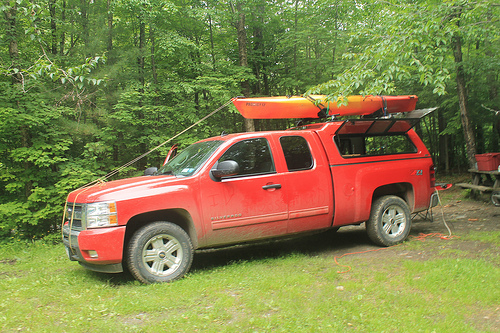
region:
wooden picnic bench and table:
[452, 165, 497, 198]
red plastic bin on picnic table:
[470, 147, 497, 168]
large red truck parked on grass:
[61, 112, 436, 282]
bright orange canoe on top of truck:
[231, 90, 416, 115]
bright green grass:
[0, 216, 499, 328]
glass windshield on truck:
[155, 140, 216, 170]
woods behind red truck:
[1, 0, 492, 235]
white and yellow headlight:
[80, 200, 116, 225]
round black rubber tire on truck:
[121, 217, 191, 279]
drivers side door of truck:
[193, 133, 288, 248]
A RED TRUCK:
[53, 97, 448, 286]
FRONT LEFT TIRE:
[121, 215, 199, 292]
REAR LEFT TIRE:
[362, 198, 440, 251]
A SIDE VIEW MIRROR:
[208, 142, 244, 187]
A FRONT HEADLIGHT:
[81, 197, 132, 232]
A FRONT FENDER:
[35, 223, 138, 271]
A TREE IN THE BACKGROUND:
[429, 44, 499, 149]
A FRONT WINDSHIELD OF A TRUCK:
[153, 133, 226, 180]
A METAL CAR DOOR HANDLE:
[260, 173, 285, 198]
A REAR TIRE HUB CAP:
[381, 198, 413, 243]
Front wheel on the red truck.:
[122, 225, 198, 281]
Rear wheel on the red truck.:
[362, 194, 414, 248]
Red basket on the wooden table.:
[473, 151, 499, 170]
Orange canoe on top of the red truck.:
[231, 96, 419, 117]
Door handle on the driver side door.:
[259, 181, 288, 190]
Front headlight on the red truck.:
[86, 203, 118, 225]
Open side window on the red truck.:
[337, 118, 421, 135]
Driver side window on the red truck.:
[213, 139, 275, 179]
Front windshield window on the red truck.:
[156, 134, 218, 174]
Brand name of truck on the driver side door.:
[206, 211, 248, 222]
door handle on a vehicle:
[256, 178, 289, 195]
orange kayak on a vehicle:
[218, 83, 433, 131]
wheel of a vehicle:
[113, 215, 203, 290]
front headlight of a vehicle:
[83, 196, 123, 235]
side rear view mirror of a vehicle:
[206, 156, 243, 188]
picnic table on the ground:
[451, 155, 498, 206]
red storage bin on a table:
[468, 148, 497, 181]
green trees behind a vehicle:
[68, 21, 213, 194]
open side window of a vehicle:
[328, 115, 425, 165]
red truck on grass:
[41, 107, 471, 297]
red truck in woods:
[58, 46, 472, 286]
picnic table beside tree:
[463, 134, 494, 214]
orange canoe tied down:
[227, 73, 424, 143]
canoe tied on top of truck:
[212, 68, 444, 229]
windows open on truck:
[315, 91, 440, 162]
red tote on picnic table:
[464, 136, 497, 201]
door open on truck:
[161, 126, 207, 199]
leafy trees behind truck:
[23, 53, 485, 178]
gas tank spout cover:
[338, 175, 363, 218]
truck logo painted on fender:
[404, 161, 439, 188]